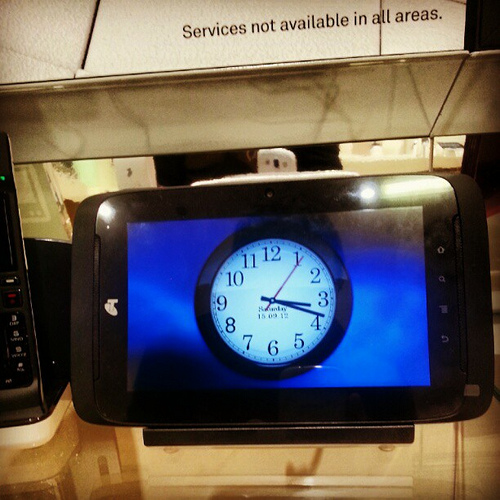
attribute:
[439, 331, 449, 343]
button — control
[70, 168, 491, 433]
telephone — portable, black, big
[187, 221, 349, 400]
frame — round, black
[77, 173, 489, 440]
phone — cell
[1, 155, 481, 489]
tabletop — clear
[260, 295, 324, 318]
hand — second